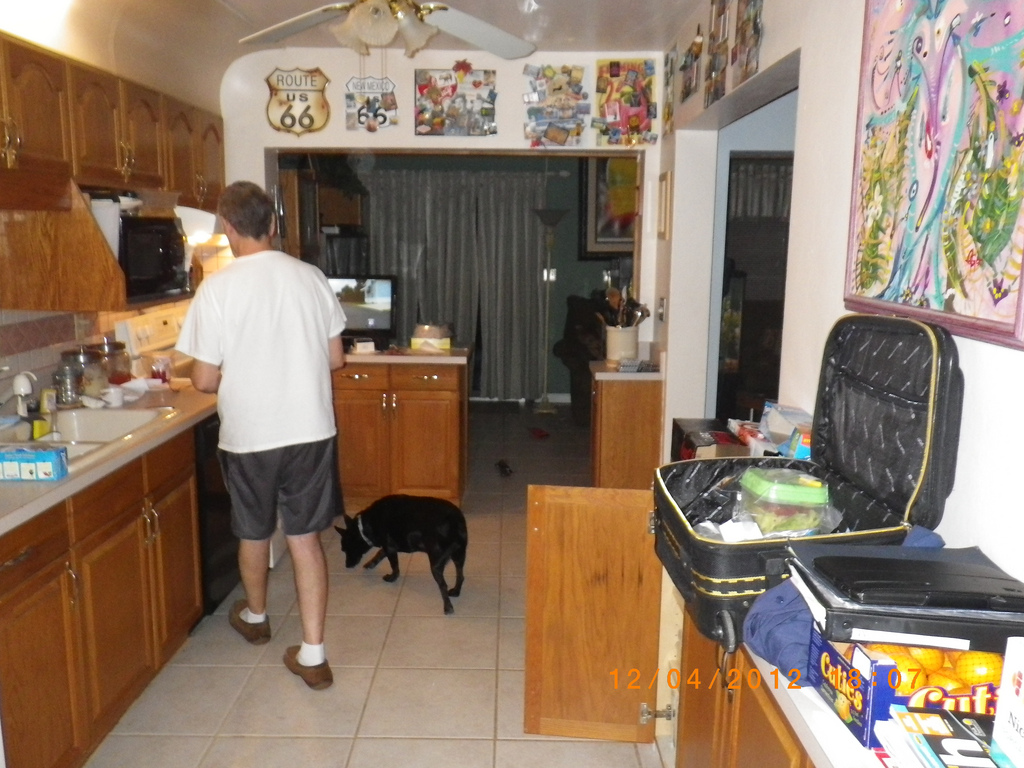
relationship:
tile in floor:
[345, 736, 497, 765] [84, 419, 680, 765]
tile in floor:
[377, 613, 501, 672] [84, 419, 680, 765]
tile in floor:
[253, 612, 394, 669] [84, 419, 680, 765]